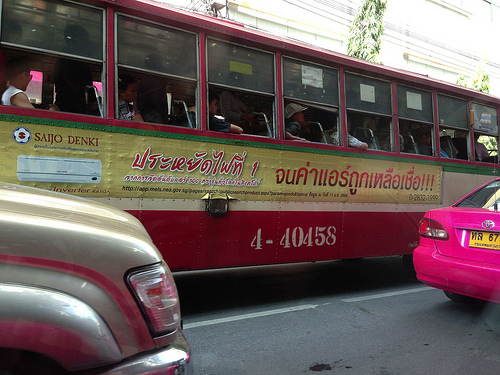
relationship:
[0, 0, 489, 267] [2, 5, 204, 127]
bus has windows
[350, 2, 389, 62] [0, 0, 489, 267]
tree behind bus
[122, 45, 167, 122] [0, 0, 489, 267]
asian people in bus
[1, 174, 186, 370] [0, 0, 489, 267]
another car next to bus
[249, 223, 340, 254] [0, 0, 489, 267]
4-40458 painted on bus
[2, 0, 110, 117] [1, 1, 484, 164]
window forming row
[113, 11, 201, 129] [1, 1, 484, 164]
window forming row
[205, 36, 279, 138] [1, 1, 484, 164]
window forming row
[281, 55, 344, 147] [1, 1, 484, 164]
window forming row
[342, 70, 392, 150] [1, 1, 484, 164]
window forming row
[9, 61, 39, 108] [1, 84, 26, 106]
person wearing shirt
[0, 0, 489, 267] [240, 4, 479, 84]
bus driving in front of building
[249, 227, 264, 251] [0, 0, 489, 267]
number painted on bus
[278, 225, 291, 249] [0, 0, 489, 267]
number painted on bus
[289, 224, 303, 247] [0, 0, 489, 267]
number painted on bus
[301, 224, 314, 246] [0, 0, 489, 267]
number painted on bus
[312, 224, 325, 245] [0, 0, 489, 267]
number painted on bus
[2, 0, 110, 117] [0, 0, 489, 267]
window built into bus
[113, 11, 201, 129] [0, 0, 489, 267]
window built into bus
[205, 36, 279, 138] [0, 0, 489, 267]
window built into bus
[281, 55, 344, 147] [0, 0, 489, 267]
window built into bus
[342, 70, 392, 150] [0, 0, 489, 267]
window built into bus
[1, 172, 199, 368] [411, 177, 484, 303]
car driving car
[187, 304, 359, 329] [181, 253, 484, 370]
white line painted on road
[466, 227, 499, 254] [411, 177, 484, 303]
license plate mounted on car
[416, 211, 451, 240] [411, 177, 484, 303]
light mounted on car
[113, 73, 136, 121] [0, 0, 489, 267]
person sitting sitting in bus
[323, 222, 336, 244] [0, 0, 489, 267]
number painted on bus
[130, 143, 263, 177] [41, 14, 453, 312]
asian characters on bus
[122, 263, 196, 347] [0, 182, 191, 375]
front headlight on car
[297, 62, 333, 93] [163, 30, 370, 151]
white paper in window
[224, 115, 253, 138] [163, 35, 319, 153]
arm on edge of window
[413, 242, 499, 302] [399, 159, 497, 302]
pink bumper on car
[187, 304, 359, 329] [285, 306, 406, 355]
white line in street